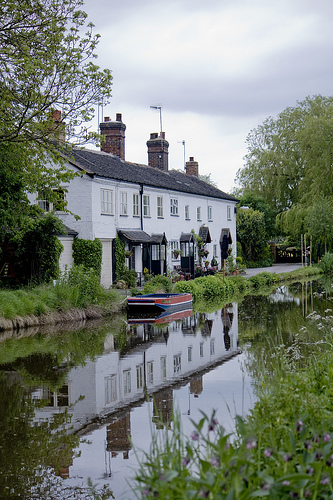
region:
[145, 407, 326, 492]
wild flowers growing at water's edge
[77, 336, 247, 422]
building reflected in the water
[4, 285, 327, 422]
a body of still water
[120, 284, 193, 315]
small boat docked at the bank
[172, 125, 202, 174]
chimney with antenna attached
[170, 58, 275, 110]
a cloudy sky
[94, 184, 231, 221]
row of windows on the building's facade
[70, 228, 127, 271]
ivy growing up the wall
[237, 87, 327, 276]
tree in a rural setting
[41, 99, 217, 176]
four chimneys on the roof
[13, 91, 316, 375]
A riverside scene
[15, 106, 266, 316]
A house is along the river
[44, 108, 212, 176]
The house has four chimneys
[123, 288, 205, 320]
A boat is on the river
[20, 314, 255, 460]
The house's reflection is in the river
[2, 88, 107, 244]
A tree is growing next to the house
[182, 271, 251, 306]
Bushes are growing on the river bank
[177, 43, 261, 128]
The sky is cloudy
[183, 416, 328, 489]
Purple flowers are growing here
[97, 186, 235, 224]
The house has many windows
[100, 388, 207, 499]
the water is clear and visible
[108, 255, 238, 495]
the water is clear and visible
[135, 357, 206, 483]
the water is clear and visible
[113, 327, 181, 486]
the water is clear and visible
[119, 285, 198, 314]
red, white and blue boat in water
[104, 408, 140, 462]
reflection of brown chimney in water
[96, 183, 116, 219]
window on white building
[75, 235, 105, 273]
ivy growing on corner of building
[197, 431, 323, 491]
tall plant with purple flowers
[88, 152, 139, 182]
dark tiles on roof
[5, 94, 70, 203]
tree limbs hanging over the water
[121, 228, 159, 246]
flat overhang on building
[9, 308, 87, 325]
dead grass on bank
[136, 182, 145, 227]
Gutter on side of building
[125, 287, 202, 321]
red, white and blue boat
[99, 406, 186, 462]
reflection of the chimneys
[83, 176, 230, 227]
second floor windows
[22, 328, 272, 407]
reflection of the house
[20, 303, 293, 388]
small body of water in front of the house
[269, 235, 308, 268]
gate to the property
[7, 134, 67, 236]
tree planted on the side of the house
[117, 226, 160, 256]
porch awning over the door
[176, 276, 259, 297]
bushes planted along the river bank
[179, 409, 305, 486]
purple flowers along the river bank